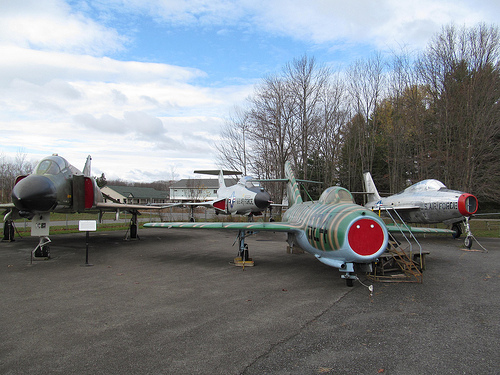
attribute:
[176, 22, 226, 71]
sky — blue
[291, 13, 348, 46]
clouds — white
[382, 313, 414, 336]
ground — concrete, gray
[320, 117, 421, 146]
trees — empty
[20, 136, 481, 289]
planes — 4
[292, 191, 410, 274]
plane — 1st, 4th, silver, green, yellow, red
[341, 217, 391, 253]
front — red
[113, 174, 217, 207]
buildings — distant, tan, blue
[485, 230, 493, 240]
grass — green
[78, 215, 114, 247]
sign — white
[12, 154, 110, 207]
plane — 2nd, green, black, dark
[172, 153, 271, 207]
plane — 3rd, yellow, silver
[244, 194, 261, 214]
force — black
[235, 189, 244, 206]
air — black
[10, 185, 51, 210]
nose — black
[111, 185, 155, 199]
roof — dark